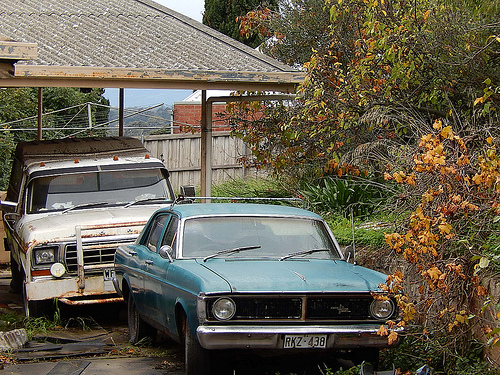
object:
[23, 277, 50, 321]
tires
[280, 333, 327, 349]
license plate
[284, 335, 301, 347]
lettering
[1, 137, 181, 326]
vehicle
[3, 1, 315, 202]
carport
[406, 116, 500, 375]
trees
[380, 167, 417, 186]
leaves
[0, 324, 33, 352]
trash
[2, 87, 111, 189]
tree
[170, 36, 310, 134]
house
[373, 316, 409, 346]
leaves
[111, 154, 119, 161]
orange lights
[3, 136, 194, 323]
truck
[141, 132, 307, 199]
fence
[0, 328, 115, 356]
debris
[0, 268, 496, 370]
ground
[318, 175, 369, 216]
plant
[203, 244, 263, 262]
windshield wipers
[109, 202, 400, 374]
car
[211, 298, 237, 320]
light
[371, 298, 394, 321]
light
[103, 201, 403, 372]
vehicle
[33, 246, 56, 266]
light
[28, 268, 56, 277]
light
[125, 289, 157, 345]
tire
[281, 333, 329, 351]
plate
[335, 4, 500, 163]
tree